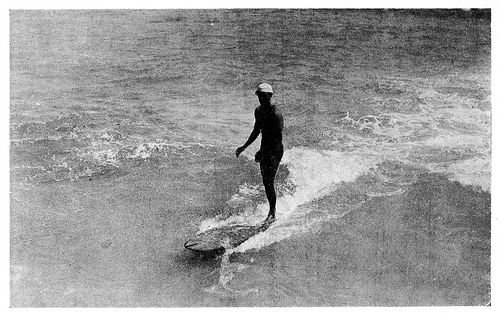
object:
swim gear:
[243, 104, 285, 221]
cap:
[255, 81, 274, 97]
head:
[254, 82, 274, 106]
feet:
[262, 215, 276, 224]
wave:
[192, 69, 491, 295]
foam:
[193, 73, 490, 255]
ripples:
[10, 9, 495, 94]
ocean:
[10, 8, 492, 307]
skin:
[263, 94, 270, 99]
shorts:
[258, 143, 284, 216]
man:
[234, 81, 287, 224]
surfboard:
[183, 223, 278, 253]